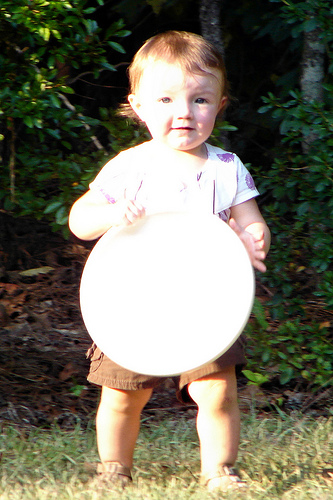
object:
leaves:
[315, 182, 325, 192]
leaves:
[44, 201, 62, 215]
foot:
[198, 465, 249, 495]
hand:
[113, 199, 144, 228]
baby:
[65, 30, 273, 483]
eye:
[161, 97, 171, 104]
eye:
[193, 97, 208, 104]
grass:
[309, 435, 320, 460]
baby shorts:
[88, 346, 249, 395]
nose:
[177, 98, 193, 119]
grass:
[3, 478, 14, 499]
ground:
[1, 387, 310, 498]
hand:
[227, 216, 266, 274]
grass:
[12, 431, 24, 446]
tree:
[298, 0, 328, 310]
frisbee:
[78, 201, 255, 378]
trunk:
[305, 12, 321, 82]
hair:
[115, 30, 225, 131]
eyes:
[159, 97, 173, 105]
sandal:
[83, 461, 134, 497]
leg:
[187, 362, 242, 492]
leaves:
[242, 367, 262, 381]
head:
[116, 27, 228, 150]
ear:
[127, 94, 144, 124]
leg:
[87, 379, 151, 498]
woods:
[201, 1, 222, 32]